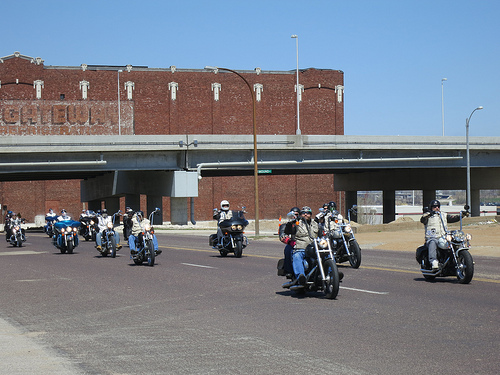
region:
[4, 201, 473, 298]
people are riding the motorcycle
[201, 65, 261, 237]
a tall street lamp on the side of the road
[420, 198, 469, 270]
the person is wearing white shoe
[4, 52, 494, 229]
a red color building behind the bridge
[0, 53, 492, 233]
the bridge is in front of the red building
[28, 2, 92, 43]
white clouds in blue sky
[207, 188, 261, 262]
man on motorcycle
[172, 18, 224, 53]
white clouds in blue sky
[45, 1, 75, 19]
white clouds in blue sky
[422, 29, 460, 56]
white clouds in blue sky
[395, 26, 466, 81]
white clouds in blue sky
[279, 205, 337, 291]
a bike on the road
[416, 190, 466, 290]
a bike on the road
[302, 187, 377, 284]
a bike on the road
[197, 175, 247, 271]
a bike on the road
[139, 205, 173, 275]
a bike on the road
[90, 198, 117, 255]
a bike on the road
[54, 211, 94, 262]
a bike on the road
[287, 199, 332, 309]
a person on a bikea person on a bike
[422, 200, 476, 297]
a person on a bike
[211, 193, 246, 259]
a person on a bike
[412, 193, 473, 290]
this is a motorcycle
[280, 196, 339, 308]
this is a motorcycle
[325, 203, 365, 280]
this is a motorcycle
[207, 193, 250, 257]
this is a motorcycle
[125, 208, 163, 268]
this is a motorcycle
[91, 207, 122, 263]
this is a motorcycle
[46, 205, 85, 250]
this is a motorcycle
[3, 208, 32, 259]
this is a motorcycle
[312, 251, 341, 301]
this is a tyre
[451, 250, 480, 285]
this is a tyre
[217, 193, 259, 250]
man on bike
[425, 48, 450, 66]
green and yellow leaves in tree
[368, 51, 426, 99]
green and yellow leaves in tree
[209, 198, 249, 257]
the person is riding the motorcycle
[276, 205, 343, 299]
the person is riding the motorcycle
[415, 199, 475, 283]
the person is riding the motorcycle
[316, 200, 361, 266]
the person is riding the motorcycle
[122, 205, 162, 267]
the person is riding the motorcycle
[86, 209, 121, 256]
the person is riding the motorcycle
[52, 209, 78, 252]
the person is riding the motorcycle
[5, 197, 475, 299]
the group of people riding their motorcycles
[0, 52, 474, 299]
the large building behind the group of people riding their motorcycles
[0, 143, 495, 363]
many bikes on the street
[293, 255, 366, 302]
front of the bike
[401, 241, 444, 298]
back of the bike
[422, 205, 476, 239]
handlebars on the bike